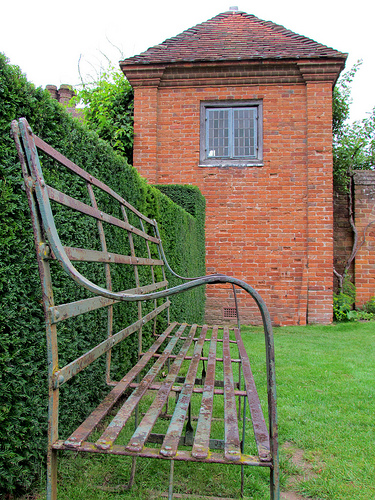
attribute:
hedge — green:
[1, 178, 208, 489]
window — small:
[199, 98, 264, 168]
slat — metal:
[246, 321, 280, 456]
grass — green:
[302, 342, 360, 429]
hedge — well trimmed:
[2, 54, 205, 381]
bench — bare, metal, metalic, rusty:
[7, 114, 286, 499]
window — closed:
[199, 101, 253, 162]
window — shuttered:
[200, 100, 263, 165]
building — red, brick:
[118, 4, 348, 323]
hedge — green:
[0, 53, 205, 497]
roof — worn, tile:
[119, 1, 353, 69]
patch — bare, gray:
[280, 436, 315, 496]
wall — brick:
[354, 184, 374, 313]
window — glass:
[232, 104, 257, 158]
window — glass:
[203, 106, 231, 159]